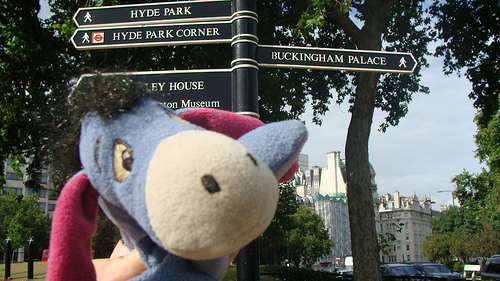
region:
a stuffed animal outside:
[39, 1, 339, 274]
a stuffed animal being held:
[28, 51, 319, 273]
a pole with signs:
[74, 7, 367, 260]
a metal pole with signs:
[162, 15, 272, 209]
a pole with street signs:
[161, 18, 368, 218]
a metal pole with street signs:
[189, 12, 293, 159]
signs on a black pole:
[173, 12, 295, 148]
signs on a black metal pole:
[186, 18, 371, 247]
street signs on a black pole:
[112, 9, 416, 256]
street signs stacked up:
[165, 19, 342, 219]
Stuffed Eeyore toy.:
[46, 71, 308, 279]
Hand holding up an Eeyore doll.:
[46, 74, 310, 279]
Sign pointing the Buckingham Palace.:
[230, 39, 417, 72]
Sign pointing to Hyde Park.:
[73, 0, 258, 30]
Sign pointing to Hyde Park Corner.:
[69, 15, 259, 50]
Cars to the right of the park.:
[312, 255, 499, 280]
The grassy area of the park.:
[0, 261, 352, 279]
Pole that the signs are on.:
[232, 0, 261, 280]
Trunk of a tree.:
[323, 2, 393, 279]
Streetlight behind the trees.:
[433, 188, 458, 213]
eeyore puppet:
[48, 77, 342, 270]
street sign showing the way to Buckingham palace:
[268, 45, 420, 85]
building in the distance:
[369, 188, 439, 266]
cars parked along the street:
[387, 259, 467, 279]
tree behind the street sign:
[328, 18, 398, 260]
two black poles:
[4, 232, 34, 279]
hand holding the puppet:
[87, 228, 154, 279]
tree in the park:
[4, 185, 44, 260]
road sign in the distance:
[331, 248, 342, 275]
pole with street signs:
[221, 2, 265, 99]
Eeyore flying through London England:
[34, 2, 423, 277]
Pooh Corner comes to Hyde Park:
[25, 0, 335, 279]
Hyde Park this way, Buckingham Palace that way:
[32, 1, 439, 78]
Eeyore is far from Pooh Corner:
[29, 70, 340, 278]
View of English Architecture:
[321, 148, 498, 278]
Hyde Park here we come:
[48, 3, 246, 75]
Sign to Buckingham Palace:
[239, 36, 424, 84]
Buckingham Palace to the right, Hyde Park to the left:
[64, 3, 434, 85]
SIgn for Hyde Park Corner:
[63, 26, 253, 46]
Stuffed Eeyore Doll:
[31, 64, 331, 279]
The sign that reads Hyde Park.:
[72, 3, 232, 17]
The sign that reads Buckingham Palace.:
[267, 45, 416, 68]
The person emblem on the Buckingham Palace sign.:
[399, 53, 409, 68]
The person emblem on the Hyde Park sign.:
[80, 12, 91, 21]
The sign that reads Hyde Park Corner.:
[72, 28, 234, 49]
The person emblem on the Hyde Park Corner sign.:
[76, 32, 90, 44]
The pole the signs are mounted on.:
[233, 2, 262, 279]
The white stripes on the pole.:
[232, 9, 257, 116]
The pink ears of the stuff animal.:
[12, 103, 302, 273]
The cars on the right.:
[298, 250, 498, 278]